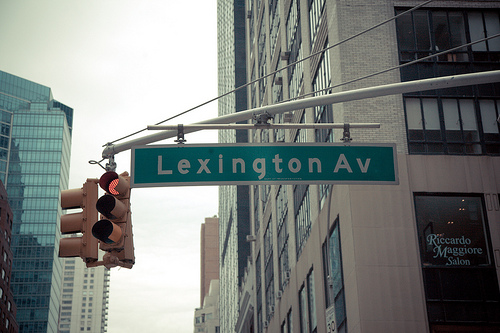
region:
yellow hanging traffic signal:
[83, 157, 155, 292]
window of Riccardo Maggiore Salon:
[390, 178, 490, 328]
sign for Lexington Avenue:
[120, 126, 405, 186]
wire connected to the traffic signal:
[81, 140, 127, 177]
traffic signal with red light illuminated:
[81, 138, 146, 280]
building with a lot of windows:
[6, 91, 76, 327]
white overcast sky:
[1, 1, 228, 327]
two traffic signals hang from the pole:
[42, 138, 202, 309]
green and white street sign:
[118, 122, 418, 202]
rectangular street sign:
[111, 132, 456, 205]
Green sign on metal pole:
[112, 122, 449, 192]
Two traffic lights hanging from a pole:
[39, 173, 158, 272]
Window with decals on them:
[404, 190, 499, 331]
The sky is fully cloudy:
[37, 5, 198, 92]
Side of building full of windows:
[251, 216, 394, 330]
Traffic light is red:
[87, 151, 168, 275]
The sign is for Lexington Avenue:
[122, 122, 430, 197]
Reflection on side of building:
[12, 188, 53, 331]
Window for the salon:
[409, 187, 496, 303]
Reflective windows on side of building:
[2, 81, 74, 182]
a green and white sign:
[96, 61, 497, 294]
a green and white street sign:
[72, 66, 487, 238]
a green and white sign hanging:
[114, 57, 497, 264]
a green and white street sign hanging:
[140, 67, 497, 245]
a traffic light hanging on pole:
[21, 77, 168, 323]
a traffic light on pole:
[47, 90, 247, 298]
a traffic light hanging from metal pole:
[30, 81, 262, 331]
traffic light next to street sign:
[29, 74, 376, 327]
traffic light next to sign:
[40, 67, 497, 328]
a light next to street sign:
[28, 56, 475, 330]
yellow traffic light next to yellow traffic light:
[56, 180, 100, 267]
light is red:
[108, 180, 120, 193]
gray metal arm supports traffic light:
[101, 67, 498, 152]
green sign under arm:
[126, 141, 404, 187]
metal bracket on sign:
[175, 124, 187, 143]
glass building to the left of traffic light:
[1, 70, 63, 331]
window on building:
[413, 191, 498, 330]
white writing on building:
[426, 229, 486, 268]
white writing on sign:
[157, 151, 373, 177]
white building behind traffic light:
[57, 215, 109, 332]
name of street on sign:
[122, 137, 404, 196]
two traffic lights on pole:
[54, 139, 138, 279]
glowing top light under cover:
[97, 171, 125, 199]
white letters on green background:
[181, 150, 324, 182]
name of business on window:
[422, 225, 484, 272]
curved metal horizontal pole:
[233, 71, 434, 132]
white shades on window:
[408, 91, 478, 140]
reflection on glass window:
[10, 137, 42, 256]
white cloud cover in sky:
[105, 16, 197, 92]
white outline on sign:
[382, 137, 402, 191]